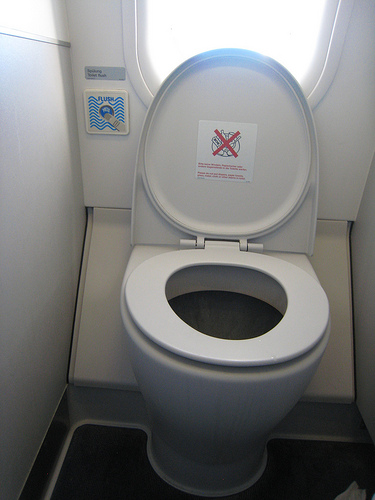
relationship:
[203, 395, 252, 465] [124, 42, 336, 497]
stains on toilet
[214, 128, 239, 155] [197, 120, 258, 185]
letters on sticker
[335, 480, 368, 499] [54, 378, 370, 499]
paper on board